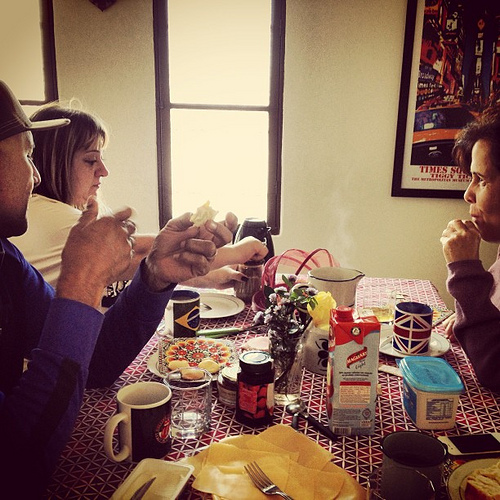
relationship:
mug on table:
[114, 384, 176, 459] [117, 312, 460, 497]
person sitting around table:
[423, 110, 498, 405] [9, 197, 498, 499]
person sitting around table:
[18, 73, 272, 322] [9, 197, 498, 499]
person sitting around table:
[4, 70, 236, 487] [9, 197, 498, 499]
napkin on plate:
[284, 458, 344, 496] [211, 451, 366, 498]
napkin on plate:
[184, 440, 292, 499] [211, 451, 366, 498]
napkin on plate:
[216, 433, 298, 460] [211, 451, 366, 498]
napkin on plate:
[256, 424, 333, 469] [211, 451, 366, 498]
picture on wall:
[391, 0, 498, 197] [50, 2, 499, 311]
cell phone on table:
[436, 433, 499, 458] [39, 273, 499, 498]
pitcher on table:
[305, 264, 364, 313] [39, 273, 499, 498]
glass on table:
[167, 361, 214, 443] [85, 259, 491, 496]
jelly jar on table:
[238, 345, 280, 422] [351, 276, 440, 308]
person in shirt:
[4, 96, 267, 298] [15, 191, 91, 296]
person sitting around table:
[437, 110, 499, 398] [362, 270, 445, 304]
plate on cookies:
[144, 332, 243, 389] [164, 338, 233, 383]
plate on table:
[144, 332, 243, 389] [7, 262, 498, 492]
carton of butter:
[324, 303, 379, 432] [398, 355, 464, 430]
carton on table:
[324, 303, 379, 432] [39, 273, 499, 498]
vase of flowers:
[260, 330, 310, 420] [244, 267, 324, 377]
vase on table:
[260, 330, 310, 420] [39, 273, 499, 498]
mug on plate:
[378, 290, 441, 355] [373, 328, 454, 362]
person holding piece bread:
[0, 75, 238, 487] [152, 196, 227, 292]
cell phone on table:
[395, 427, 496, 471] [268, 347, 415, 452]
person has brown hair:
[4, 96, 267, 298] [46, 131, 73, 162]